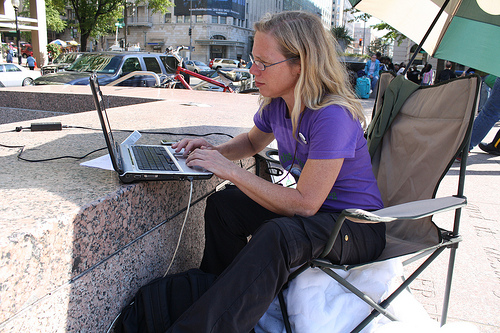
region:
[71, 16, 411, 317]
a woman typing on her laptop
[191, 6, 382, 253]
a woman wearing a purple t-shirt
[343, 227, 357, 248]
a silver snap on a pocket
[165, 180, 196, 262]
a white cord hanging down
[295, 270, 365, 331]
a white blanket under the chair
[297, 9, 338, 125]
blond hair growing from a head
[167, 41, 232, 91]
a red bicycle next to the woman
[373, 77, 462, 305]
a brown folding chair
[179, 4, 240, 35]
a building across the street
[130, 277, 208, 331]
a black back pack leaning against a leg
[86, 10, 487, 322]
woman working on a laptop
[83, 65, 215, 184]
laptop computer on stone wall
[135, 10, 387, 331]
woman working outdoors on laptop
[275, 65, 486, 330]
tan colored folding chair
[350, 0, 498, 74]
umbrella keeping sun off woman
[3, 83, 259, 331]
stone wall on which laptop is sitting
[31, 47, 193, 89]
blue vehicle on street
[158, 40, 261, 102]
red bicycle parked beside stone wall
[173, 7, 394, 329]
young woman with glasses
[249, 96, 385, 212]
periwinkle blue tee shirt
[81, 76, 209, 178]
this is a laptop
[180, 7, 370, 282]
this is a woman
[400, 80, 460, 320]
this is a chair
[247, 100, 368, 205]
the woman is wearing a purple t-shirt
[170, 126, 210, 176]
the woman is typing on the keyboard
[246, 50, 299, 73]
this is a pair of spectacles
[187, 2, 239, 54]
this is a building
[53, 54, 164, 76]
this is a car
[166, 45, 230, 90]
this is a bicycle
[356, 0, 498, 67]
this is an umbrella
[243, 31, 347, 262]
The person is wearing a shirt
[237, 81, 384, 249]
The person is wearing a purple shirt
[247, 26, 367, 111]
The person has blond hair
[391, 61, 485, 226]
The person is sitting in a chair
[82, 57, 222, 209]
The person is on a computer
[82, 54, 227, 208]
The computer is black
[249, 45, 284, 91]
The person has glasses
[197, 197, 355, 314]
The person's pants are black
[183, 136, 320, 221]
The person has arms,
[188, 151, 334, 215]
The person's arms are peach colored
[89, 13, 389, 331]
Woman using a laptop computer.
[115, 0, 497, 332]
Woman sitting in a chair.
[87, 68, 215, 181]
Open laptop computer.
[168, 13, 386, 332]
Woman in a purple shirt.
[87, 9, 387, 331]
Blonde woman using a laptop computer.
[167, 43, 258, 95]
Red bicycle.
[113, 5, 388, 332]
Woman with a black backpack at her feet.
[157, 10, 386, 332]
Person in a purple shirt and black pants.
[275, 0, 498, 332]
Folding chair with an umbrella for shade.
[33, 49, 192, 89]
Blue SUV parked on the street.